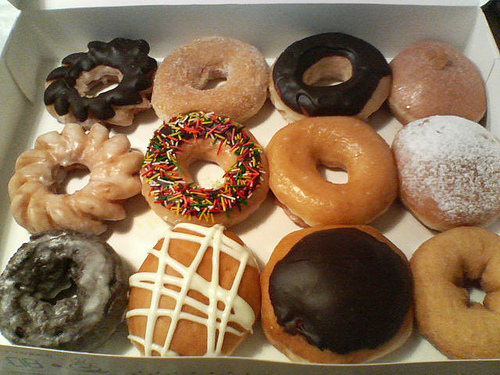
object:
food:
[0, 32, 499, 363]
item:
[140, 113, 265, 223]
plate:
[157, 5, 301, 44]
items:
[8, 38, 393, 234]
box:
[0, 0, 498, 374]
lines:
[126, 224, 261, 359]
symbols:
[23, 351, 94, 369]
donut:
[264, 115, 397, 227]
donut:
[272, 32, 390, 117]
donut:
[390, 41, 485, 119]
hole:
[313, 157, 351, 185]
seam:
[0, 57, 35, 108]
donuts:
[0, 110, 412, 360]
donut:
[396, 116, 500, 223]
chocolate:
[272, 30, 390, 117]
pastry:
[385, 40, 487, 125]